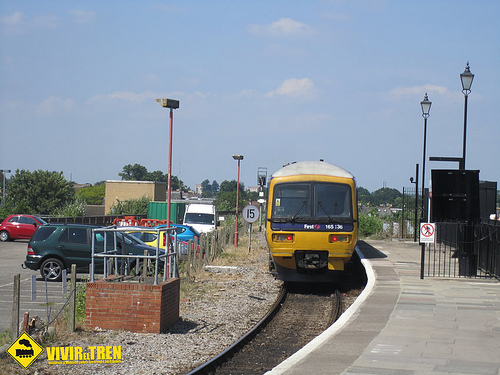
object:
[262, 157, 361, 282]
train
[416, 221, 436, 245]
sign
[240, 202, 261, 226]
sign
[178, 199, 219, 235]
van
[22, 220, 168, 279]
suv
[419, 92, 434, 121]
light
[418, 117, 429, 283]
pole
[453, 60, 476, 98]
light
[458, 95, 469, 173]
pole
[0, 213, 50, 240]
car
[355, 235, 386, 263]
shadow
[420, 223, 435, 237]
no walking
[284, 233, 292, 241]
red light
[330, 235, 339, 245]
red light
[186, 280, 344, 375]
tracks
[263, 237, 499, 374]
platform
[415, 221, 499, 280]
fence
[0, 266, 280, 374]
gravel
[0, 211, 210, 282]
cars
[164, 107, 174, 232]
pole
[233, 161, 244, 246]
pole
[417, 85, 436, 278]
lamppost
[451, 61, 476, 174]
lamppost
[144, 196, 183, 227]
storage container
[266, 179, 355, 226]
windshield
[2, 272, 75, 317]
white lines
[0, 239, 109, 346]
parking lot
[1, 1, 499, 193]
sky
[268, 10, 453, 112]
clouds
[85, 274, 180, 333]
structure